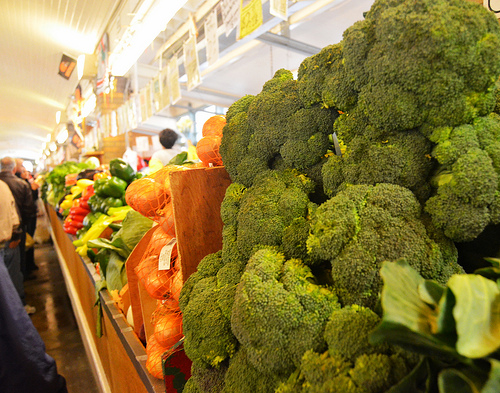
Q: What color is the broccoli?
A: Green.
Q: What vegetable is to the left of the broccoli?
A: Onions.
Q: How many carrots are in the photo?
A: Zero.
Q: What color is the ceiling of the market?
A: White.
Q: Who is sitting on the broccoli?
A: No one.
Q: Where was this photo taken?
A: In the produce section.